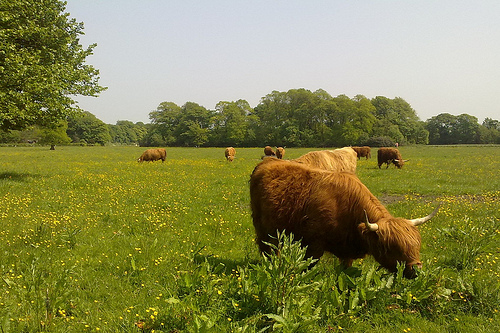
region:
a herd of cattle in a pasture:
[115, 137, 437, 288]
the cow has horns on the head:
[350, 200, 441, 235]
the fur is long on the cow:
[325, 165, 420, 250]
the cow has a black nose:
[400, 261, 420, 277]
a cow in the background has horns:
[375, 145, 406, 166]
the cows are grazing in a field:
[107, 140, 430, 292]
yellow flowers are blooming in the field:
[77, 175, 188, 229]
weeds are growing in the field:
[176, 231, 404, 331]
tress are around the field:
[4, 43, 498, 148]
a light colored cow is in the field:
[295, 144, 359, 184]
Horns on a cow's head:
[358, 208, 432, 231]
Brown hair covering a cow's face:
[377, 222, 423, 261]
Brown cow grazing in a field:
[243, 158, 448, 280]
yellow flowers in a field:
[3, 177, 231, 235]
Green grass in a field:
[8, 143, 496, 332]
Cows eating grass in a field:
[123, 138, 415, 180]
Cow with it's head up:
[274, 144, 286, 160]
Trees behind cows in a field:
[143, 87, 499, 147]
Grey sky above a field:
[84, 0, 498, 97]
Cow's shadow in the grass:
[187, 251, 264, 278]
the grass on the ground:
[2, 135, 487, 330]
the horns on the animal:
[364, 203, 442, 238]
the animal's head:
[360, 208, 434, 279]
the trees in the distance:
[11, 89, 498, 146]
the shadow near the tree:
[2, 164, 59, 186]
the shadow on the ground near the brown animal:
[183, 247, 286, 278]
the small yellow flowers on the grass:
[12, 150, 497, 330]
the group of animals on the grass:
[128, 142, 436, 281]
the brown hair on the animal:
[250, 158, 432, 279]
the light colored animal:
[280, 145, 357, 177]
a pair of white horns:
[361, 207, 439, 231]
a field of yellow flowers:
[0, 166, 230, 331]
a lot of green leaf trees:
[142, 80, 428, 147]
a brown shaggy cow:
[248, 155, 443, 281]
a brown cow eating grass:
[248, 156, 440, 281]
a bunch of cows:
[135, 136, 432, 278]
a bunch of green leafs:
[1, 0, 105, 135]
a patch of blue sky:
[114, 0, 473, 85]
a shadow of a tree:
[0, 163, 55, 185]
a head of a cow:
[356, 204, 444, 278]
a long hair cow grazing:
[242, 153, 435, 307]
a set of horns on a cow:
[351, 201, 441, 231]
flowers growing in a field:
[13, 170, 135, 256]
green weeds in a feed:
[197, 228, 324, 323]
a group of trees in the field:
[126, 77, 432, 143]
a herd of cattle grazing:
[81, 120, 424, 291]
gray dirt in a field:
[387, 182, 482, 208]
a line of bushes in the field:
[6, 140, 87, 151]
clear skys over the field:
[118, 6, 466, 91]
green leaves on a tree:
[14, 10, 121, 121]